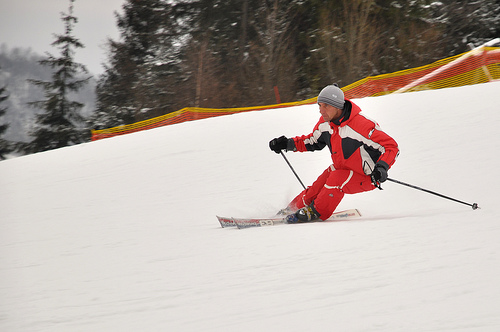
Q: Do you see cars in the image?
A: No, there are no cars.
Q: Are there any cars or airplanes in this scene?
A: No, there are no cars or airplanes.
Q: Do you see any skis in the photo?
A: Yes, there are skis.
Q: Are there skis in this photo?
A: Yes, there are skis.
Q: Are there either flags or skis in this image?
A: Yes, there are skis.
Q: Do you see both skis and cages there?
A: No, there are skis but no cages.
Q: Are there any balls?
A: No, there are no balls.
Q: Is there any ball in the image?
A: No, there are no balls.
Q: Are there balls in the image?
A: No, there are no balls.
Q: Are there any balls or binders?
A: No, there are no balls or binders.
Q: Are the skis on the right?
A: Yes, the skis are on the right of the image.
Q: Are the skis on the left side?
A: No, the skis are on the right of the image.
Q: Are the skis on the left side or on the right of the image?
A: The skis are on the right of the image.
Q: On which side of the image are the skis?
A: The skis are on the right of the image.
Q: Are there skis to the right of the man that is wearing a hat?
A: Yes, there are skis to the right of the man.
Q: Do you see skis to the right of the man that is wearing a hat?
A: Yes, there are skis to the right of the man.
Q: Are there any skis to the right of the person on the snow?
A: Yes, there are skis to the right of the man.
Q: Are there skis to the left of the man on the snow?
A: No, the skis are to the right of the man.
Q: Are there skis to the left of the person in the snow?
A: No, the skis are to the right of the man.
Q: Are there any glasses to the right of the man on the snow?
A: No, there are skis to the right of the man.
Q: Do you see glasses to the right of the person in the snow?
A: No, there are skis to the right of the man.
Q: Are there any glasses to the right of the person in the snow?
A: No, there are skis to the right of the man.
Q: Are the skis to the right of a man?
A: Yes, the skis are to the right of a man.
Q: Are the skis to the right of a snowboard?
A: No, the skis are to the right of a man.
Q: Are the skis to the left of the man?
A: No, the skis are to the right of the man.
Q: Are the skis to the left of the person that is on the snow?
A: No, the skis are to the right of the man.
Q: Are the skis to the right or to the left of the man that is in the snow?
A: The skis are to the right of the man.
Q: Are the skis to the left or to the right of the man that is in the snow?
A: The skis are to the right of the man.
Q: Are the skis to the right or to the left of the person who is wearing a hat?
A: The skis are to the right of the man.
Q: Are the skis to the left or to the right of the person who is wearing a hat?
A: The skis are to the right of the man.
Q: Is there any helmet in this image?
A: No, there are no helmets.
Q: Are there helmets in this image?
A: No, there are no helmets.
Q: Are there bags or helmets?
A: No, there are no helmets or bags.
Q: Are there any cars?
A: No, there are no cars.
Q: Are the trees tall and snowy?
A: Yes, the trees are tall and snowy.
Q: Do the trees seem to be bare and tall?
A: No, the trees are tall but snowy.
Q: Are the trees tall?
A: Yes, the trees are tall.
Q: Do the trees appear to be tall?
A: Yes, the trees are tall.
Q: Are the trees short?
A: No, the trees are tall.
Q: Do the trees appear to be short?
A: No, the trees are tall.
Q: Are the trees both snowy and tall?
A: Yes, the trees are snowy and tall.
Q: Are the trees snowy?
A: Yes, the trees are snowy.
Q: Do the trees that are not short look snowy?
A: Yes, the trees are snowy.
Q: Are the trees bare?
A: No, the trees are snowy.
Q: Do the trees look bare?
A: No, the trees are snowy.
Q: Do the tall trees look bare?
A: No, the trees are snowy.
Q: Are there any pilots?
A: No, there are no pilots.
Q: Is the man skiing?
A: Yes, the man is skiing.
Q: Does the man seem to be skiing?
A: Yes, the man is skiing.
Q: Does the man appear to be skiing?
A: Yes, the man is skiing.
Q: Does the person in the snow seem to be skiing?
A: Yes, the man is skiing.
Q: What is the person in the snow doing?
A: The man is skiing.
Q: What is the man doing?
A: The man is skiing.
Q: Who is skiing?
A: The man is skiing.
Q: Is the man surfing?
A: No, the man is skiing.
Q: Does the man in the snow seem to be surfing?
A: No, the man is skiing.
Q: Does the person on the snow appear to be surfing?
A: No, the man is skiing.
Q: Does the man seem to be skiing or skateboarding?
A: The man is skiing.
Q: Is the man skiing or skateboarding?
A: The man is skiing.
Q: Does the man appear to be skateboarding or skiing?
A: The man is skiing.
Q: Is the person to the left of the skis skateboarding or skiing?
A: The man is skiing.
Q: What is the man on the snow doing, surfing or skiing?
A: The man is skiing.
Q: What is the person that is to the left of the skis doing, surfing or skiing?
A: The man is skiing.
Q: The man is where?
A: The man is in the snow.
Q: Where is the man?
A: The man is in the snow.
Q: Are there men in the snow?
A: Yes, there is a man in the snow.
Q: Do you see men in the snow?
A: Yes, there is a man in the snow.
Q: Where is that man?
A: The man is on the snow.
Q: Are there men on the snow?
A: Yes, there is a man on the snow.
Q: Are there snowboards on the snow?
A: No, there is a man on the snow.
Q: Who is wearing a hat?
A: The man is wearing a hat.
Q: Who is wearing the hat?
A: The man is wearing a hat.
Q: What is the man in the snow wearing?
A: The man is wearing a hat.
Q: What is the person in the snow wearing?
A: The man is wearing a hat.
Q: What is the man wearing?
A: The man is wearing a hat.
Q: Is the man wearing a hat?
A: Yes, the man is wearing a hat.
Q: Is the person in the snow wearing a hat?
A: Yes, the man is wearing a hat.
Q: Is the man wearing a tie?
A: No, the man is wearing a hat.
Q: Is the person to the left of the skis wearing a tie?
A: No, the man is wearing a hat.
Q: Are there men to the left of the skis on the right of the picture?
A: Yes, there is a man to the left of the skis.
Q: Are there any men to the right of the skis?
A: No, the man is to the left of the skis.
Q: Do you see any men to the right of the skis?
A: No, the man is to the left of the skis.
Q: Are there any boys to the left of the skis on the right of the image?
A: No, there is a man to the left of the skis.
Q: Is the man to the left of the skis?
A: Yes, the man is to the left of the skis.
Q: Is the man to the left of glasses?
A: No, the man is to the left of the skis.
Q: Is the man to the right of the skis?
A: No, the man is to the left of the skis.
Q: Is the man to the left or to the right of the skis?
A: The man is to the left of the skis.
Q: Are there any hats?
A: Yes, there is a hat.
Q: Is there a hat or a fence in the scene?
A: Yes, there is a hat.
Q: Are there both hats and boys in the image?
A: No, there is a hat but no boys.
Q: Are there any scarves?
A: No, there are no scarves.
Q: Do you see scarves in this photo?
A: No, there are no scarves.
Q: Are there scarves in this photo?
A: No, there are no scarves.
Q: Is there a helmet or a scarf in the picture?
A: No, there are no scarves or helmets.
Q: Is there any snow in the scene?
A: Yes, there is snow.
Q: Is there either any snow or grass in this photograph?
A: Yes, there is snow.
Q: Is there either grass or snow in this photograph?
A: Yes, there is snow.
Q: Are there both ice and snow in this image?
A: No, there is snow but no ice.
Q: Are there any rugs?
A: No, there are no rugs.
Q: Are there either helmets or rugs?
A: No, there are no rugs or helmets.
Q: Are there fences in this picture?
A: Yes, there is a fence.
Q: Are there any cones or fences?
A: Yes, there is a fence.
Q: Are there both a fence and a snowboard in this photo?
A: No, there is a fence but no snowboards.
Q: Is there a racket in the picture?
A: No, there are no rackets.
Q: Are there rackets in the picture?
A: No, there are no rackets.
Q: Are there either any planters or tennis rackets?
A: No, there are no tennis rackets or planters.